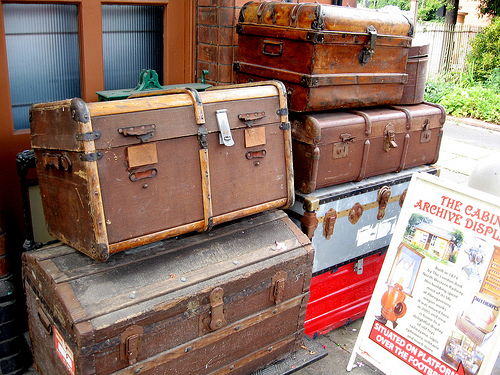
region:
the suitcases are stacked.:
[231, 5, 450, 342]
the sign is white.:
[340, 157, 498, 372]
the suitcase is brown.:
[24, 68, 301, 270]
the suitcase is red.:
[297, 238, 395, 337]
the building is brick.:
[195, 3, 270, 91]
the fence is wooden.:
[404, 16, 487, 87]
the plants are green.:
[421, 62, 498, 124]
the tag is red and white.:
[42, 322, 78, 374]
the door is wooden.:
[0, 1, 205, 139]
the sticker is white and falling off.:
[352, 210, 399, 247]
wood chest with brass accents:
[232, 1, 416, 111]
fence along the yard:
[424, 16, 486, 79]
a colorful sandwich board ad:
[343, 160, 498, 374]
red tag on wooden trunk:
[43, 319, 80, 374]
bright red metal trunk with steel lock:
[302, 246, 419, 342]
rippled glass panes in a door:
[1, 0, 205, 140]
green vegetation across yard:
[426, 14, 499, 129]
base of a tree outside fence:
[436, 0, 466, 87]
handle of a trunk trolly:
[11, 139, 53, 276]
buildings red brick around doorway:
[191, 1, 248, 92]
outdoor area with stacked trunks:
[0, 1, 498, 373]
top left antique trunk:
[28, 80, 295, 262]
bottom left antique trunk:
[22, 208, 316, 374]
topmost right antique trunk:
[232, 0, 414, 113]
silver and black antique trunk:
[284, 164, 441, 279]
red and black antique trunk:
[304, 246, 392, 339]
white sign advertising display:
[345, 168, 498, 373]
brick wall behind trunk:
[196, 1, 237, 85]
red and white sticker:
[51, 324, 76, 374]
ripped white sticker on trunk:
[355, 213, 397, 248]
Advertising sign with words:
[401, 180, 487, 367]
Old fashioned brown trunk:
[48, 84, 345, 244]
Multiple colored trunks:
[287, 100, 410, 309]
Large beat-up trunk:
[23, 232, 335, 366]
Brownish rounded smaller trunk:
[231, 8, 447, 114]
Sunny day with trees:
[413, 8, 498, 172]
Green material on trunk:
[93, 49, 208, 106]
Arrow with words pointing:
[364, 317, 461, 374]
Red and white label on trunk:
[22, 336, 122, 371]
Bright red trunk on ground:
[290, 241, 397, 326]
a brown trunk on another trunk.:
[31, 63, 303, 274]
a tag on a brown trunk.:
[210, 103, 236, 162]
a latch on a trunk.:
[195, 282, 247, 344]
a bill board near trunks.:
[328, 171, 497, 374]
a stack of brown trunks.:
[25, 1, 447, 373]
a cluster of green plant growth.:
[424, 0, 496, 127]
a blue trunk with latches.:
[296, 163, 445, 270]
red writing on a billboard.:
[413, 175, 498, 249]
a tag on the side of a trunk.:
[48, 328, 90, 374]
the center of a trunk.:
[170, 83, 223, 246]